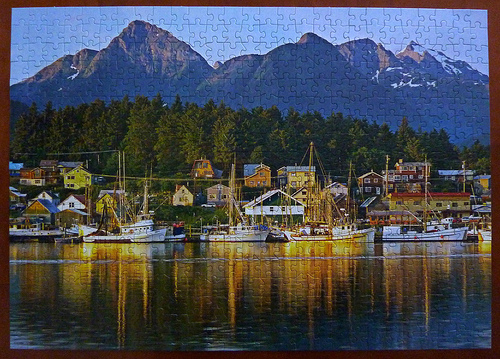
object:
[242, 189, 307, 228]
boathouse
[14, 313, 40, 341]
water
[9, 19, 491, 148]
mountains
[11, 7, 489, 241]
background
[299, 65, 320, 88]
mountain part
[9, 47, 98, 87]
mountain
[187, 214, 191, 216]
ground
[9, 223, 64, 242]
boat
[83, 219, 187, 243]
boat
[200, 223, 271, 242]
boat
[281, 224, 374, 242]
boat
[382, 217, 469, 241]
boat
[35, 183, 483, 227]
pier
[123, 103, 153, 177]
tree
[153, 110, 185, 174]
tree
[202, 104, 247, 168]
tree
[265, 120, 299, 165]
tree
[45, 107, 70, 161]
tree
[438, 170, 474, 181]
small buildings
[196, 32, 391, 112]
hill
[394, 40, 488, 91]
mountain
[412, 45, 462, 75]
snow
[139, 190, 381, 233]
shore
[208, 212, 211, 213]
ground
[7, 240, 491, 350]
reflection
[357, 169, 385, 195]
houses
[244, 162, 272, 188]
home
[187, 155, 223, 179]
building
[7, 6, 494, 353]
puzzle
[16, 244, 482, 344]
waer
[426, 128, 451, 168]
trees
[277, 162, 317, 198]
homes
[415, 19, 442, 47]
piece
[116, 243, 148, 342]
lights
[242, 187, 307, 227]
trim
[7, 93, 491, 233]
hill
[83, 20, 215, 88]
hill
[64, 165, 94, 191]
building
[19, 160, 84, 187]
building